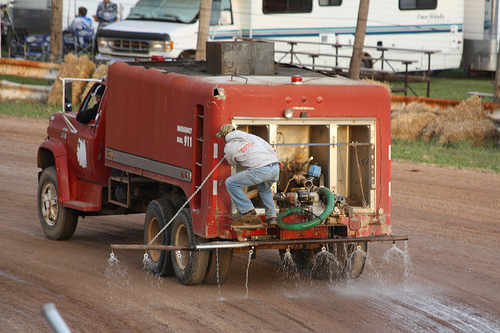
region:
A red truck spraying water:
[39, 34, 431, 274]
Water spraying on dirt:
[109, 246, 424, 301]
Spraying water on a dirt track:
[102, 238, 451, 315]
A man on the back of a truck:
[214, 118, 284, 232]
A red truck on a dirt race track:
[24, 43, 413, 278]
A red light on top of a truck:
[290, 73, 304, 86]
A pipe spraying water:
[101, 233, 415, 265]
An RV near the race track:
[94, 6, 486, 80]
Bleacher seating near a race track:
[270, 30, 452, 95]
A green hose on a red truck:
[278, 182, 335, 234]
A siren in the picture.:
[287, 73, 305, 84]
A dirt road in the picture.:
[440, 219, 476, 266]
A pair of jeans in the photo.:
[228, 169, 287, 208]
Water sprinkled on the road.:
[248, 250, 415, 290]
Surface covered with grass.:
[442, 73, 469, 103]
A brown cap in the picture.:
[215, 124, 236, 137]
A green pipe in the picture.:
[294, 217, 311, 232]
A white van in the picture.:
[283, 2, 326, 32]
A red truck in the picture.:
[16, 52, 403, 279]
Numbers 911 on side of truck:
[181, 133, 194, 149]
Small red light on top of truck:
[288, 73, 304, 84]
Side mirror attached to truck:
[61, 77, 75, 114]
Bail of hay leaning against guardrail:
[49, 51, 92, 109]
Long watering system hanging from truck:
[108, 235, 410, 258]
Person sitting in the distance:
[65, 5, 92, 33]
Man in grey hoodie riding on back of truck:
[213, 121, 279, 231]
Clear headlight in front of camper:
[148, 39, 165, 51]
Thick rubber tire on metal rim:
[35, 169, 77, 239]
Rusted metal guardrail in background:
[1, 58, 58, 103]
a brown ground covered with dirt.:
[407, 187, 489, 284]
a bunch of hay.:
[393, 88, 498, 148]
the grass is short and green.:
[421, 145, 484, 163]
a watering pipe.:
[97, 234, 423, 311]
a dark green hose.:
[275, 181, 337, 237]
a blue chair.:
[71, 31, 99, 59]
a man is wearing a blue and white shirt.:
[63, 14, 100, 33]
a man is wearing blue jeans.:
[221, 157, 283, 229]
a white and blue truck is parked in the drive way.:
[89, 0, 479, 75]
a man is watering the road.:
[1, 11, 492, 301]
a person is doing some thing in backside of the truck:
[214, 115, 286, 237]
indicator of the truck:
[287, 64, 324, 109]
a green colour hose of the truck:
[274, 175, 343, 232]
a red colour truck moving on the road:
[56, 41, 394, 268]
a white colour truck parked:
[93, 0, 464, 68]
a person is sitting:
[63, 6, 97, 56]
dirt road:
[337, 270, 485, 314]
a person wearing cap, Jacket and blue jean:
[214, 118, 291, 230]